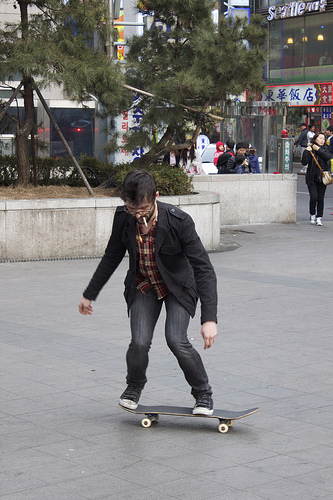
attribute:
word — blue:
[289, 87, 301, 102]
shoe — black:
[192, 400, 212, 415]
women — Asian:
[300, 131, 332, 225]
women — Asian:
[181, 141, 201, 173]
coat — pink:
[213, 140, 225, 165]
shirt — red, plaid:
[133, 211, 169, 301]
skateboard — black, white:
[119, 397, 260, 435]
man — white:
[77, 168, 223, 417]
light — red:
[71, 123, 90, 139]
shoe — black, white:
[110, 388, 148, 413]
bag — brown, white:
[320, 169, 331, 185]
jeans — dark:
[124, 284, 209, 391]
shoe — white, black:
[190, 395, 218, 419]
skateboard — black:
[125, 400, 256, 435]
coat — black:
[71, 198, 226, 323]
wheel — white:
[139, 416, 152, 429]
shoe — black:
[120, 383, 141, 412]